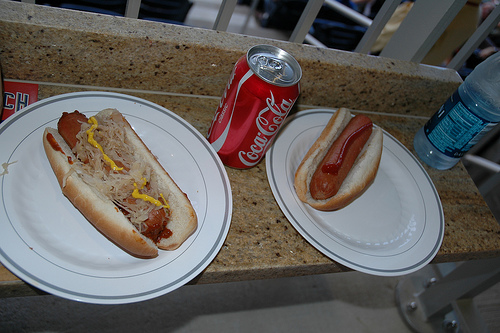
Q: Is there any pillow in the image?
A: No, there are no pillows.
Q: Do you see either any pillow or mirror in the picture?
A: No, there are no pillows or mirrors.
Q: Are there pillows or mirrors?
A: No, there are no pillows or mirrors.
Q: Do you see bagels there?
A: No, there are no bagels.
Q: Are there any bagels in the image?
A: No, there are no bagels.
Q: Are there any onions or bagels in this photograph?
A: No, there are no bagels or onions.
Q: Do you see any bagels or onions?
A: No, there are no bagels or onions.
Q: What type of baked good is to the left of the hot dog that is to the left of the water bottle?
A: The food is a bun.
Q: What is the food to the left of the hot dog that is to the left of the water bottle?
A: The food is a bun.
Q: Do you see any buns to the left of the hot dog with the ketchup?
A: Yes, there is a bun to the left of the hot dog.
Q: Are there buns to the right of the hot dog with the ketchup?
A: No, the bun is to the left of the hot dog.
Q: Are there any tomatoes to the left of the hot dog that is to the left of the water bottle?
A: No, there is a bun to the left of the hot dog.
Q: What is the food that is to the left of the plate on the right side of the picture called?
A: The food is a bun.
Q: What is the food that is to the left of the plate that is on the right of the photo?
A: The food is a bun.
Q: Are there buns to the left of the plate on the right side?
A: Yes, there is a bun to the left of the plate.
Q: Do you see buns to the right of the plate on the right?
A: No, the bun is to the left of the plate.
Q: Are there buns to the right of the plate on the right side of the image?
A: No, the bun is to the left of the plate.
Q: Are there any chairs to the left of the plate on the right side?
A: No, there is a bun to the left of the plate.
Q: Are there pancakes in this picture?
A: No, there are no pancakes.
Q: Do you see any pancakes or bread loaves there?
A: No, there are no pancakes or bread loaves.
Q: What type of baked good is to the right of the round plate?
A: The food is a bun.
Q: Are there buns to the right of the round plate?
A: Yes, there is a bun to the right of the plate.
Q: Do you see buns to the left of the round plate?
A: No, the bun is to the right of the plate.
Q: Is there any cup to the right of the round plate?
A: No, there is a bun to the right of the plate.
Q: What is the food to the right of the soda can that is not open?
A: The food is a bun.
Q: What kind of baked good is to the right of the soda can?
A: The food is a bun.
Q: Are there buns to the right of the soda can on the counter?
A: Yes, there is a bun to the right of the soda can.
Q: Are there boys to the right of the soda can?
A: No, there is a bun to the right of the soda can.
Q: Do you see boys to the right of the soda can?
A: No, there is a bun to the right of the soda can.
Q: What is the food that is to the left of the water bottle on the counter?
A: The food is a bun.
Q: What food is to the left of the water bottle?
A: The food is a bun.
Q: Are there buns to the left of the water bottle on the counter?
A: Yes, there is a bun to the left of the water bottle.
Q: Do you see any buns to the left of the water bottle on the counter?
A: Yes, there is a bun to the left of the water bottle.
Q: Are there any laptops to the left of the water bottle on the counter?
A: No, there is a bun to the left of the water bottle.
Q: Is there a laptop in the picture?
A: No, there are no laptops.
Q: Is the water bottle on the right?
A: Yes, the water bottle is on the right of the image.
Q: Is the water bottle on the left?
A: No, the water bottle is on the right of the image.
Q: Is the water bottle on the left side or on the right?
A: The water bottle is on the right of the image.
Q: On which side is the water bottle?
A: The water bottle is on the right of the image.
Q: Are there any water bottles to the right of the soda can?
A: Yes, there is a water bottle to the right of the soda can.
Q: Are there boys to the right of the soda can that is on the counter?
A: No, there is a water bottle to the right of the soda can.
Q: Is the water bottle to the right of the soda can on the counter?
A: Yes, the water bottle is to the right of the soda can.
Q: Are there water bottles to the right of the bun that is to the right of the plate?
A: Yes, there is a water bottle to the right of the bun.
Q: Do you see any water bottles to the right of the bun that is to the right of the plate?
A: Yes, there is a water bottle to the right of the bun.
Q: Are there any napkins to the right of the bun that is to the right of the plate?
A: No, there is a water bottle to the right of the bun.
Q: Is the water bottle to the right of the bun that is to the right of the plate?
A: Yes, the water bottle is to the right of the bun.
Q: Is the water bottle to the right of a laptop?
A: No, the water bottle is to the right of the bun.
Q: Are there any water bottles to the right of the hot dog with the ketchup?
A: Yes, there is a water bottle to the right of the hot dog.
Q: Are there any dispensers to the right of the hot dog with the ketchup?
A: No, there is a water bottle to the right of the hot dog.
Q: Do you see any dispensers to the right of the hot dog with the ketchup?
A: No, there is a water bottle to the right of the hot dog.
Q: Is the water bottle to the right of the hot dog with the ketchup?
A: Yes, the water bottle is to the right of the hot dog.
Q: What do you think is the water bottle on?
A: The water bottle is on the counter.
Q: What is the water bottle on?
A: The water bottle is on the counter.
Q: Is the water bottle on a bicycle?
A: No, the water bottle is on the counter.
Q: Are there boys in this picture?
A: No, there are no boys.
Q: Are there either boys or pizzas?
A: No, there are no boys or pizzas.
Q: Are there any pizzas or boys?
A: No, there are no boys or pizzas.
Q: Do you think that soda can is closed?
A: Yes, the soda can is closed.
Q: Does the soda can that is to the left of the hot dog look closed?
A: Yes, the soda can is closed.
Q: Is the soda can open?
A: No, the soda can is closed.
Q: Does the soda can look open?
A: No, the soda can is closed.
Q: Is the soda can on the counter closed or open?
A: The soda can is closed.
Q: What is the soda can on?
A: The soda can is on the counter.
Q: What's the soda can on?
A: The soda can is on the counter.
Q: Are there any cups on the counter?
A: No, there is a soda can on the counter.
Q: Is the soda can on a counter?
A: Yes, the soda can is on a counter.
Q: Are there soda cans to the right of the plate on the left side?
A: Yes, there is a soda can to the right of the plate.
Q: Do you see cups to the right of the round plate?
A: No, there is a soda can to the right of the plate.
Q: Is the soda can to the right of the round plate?
A: Yes, the soda can is to the right of the plate.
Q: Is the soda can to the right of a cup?
A: No, the soda can is to the right of the plate.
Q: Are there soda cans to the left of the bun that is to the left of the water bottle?
A: Yes, there is a soda can to the left of the bun.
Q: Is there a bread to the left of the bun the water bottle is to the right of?
A: No, there is a soda can to the left of the bun.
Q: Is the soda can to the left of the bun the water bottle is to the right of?
A: Yes, the soda can is to the left of the bun.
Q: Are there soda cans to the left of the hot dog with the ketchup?
A: Yes, there is a soda can to the left of the hot dog.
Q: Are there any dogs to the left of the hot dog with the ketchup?
A: No, there is a soda can to the left of the hot dog.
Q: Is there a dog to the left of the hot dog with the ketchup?
A: No, there is a soda can to the left of the hot dog.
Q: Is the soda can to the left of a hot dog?
A: Yes, the soda can is to the left of a hot dog.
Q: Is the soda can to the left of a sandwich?
A: No, the soda can is to the left of a hot dog.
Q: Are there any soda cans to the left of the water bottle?
A: Yes, there is a soda can to the left of the water bottle.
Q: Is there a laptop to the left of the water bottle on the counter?
A: No, there is a soda can to the left of the water bottle.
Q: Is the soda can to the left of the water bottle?
A: Yes, the soda can is to the left of the water bottle.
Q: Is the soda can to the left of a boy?
A: No, the soda can is to the left of the water bottle.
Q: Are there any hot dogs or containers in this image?
A: Yes, there is a hot dog.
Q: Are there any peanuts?
A: No, there are no peanuts.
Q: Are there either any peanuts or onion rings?
A: No, there are no peanuts or onion rings.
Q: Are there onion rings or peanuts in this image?
A: No, there are no peanuts or onion rings.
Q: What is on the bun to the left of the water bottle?
A: The hot dog is on the bun.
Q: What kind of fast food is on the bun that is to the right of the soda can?
A: The food is a hot dog.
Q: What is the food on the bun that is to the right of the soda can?
A: The food is a hot dog.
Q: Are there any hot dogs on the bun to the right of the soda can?
A: Yes, there is a hot dog on the bun.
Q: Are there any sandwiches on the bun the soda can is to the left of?
A: No, there is a hot dog on the bun.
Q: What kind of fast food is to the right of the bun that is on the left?
A: The food is a hot dog.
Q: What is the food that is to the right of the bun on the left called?
A: The food is a hot dog.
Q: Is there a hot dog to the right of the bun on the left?
A: Yes, there is a hot dog to the right of the bun.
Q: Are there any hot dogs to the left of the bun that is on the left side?
A: No, the hot dog is to the right of the bun.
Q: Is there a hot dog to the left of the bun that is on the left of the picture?
A: No, the hot dog is to the right of the bun.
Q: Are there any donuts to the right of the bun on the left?
A: No, there is a hot dog to the right of the bun.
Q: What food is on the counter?
A: The food is a hot dog.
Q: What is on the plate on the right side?
A: The hot dog is on the plate.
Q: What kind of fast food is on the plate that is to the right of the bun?
A: The food is a hot dog.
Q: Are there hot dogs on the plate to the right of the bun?
A: Yes, there is a hot dog on the plate.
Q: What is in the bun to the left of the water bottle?
A: The hot dog is in the bun.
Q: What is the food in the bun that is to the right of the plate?
A: The food is a hot dog.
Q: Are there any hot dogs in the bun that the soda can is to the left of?
A: Yes, there is a hot dog in the bun.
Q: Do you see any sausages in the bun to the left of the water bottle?
A: No, there is a hot dog in the bun.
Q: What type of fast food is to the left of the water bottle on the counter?
A: The food is a hot dog.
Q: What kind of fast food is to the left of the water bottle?
A: The food is a hot dog.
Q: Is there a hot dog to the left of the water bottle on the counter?
A: Yes, there is a hot dog to the left of the water bottle.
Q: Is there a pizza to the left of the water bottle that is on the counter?
A: No, there is a hot dog to the left of the water bottle.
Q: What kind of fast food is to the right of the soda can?
A: The food is a hot dog.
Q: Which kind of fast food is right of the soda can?
A: The food is a hot dog.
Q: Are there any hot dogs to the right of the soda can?
A: Yes, there is a hot dog to the right of the soda can.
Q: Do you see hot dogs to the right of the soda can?
A: Yes, there is a hot dog to the right of the soda can.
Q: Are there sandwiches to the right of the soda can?
A: No, there is a hot dog to the right of the soda can.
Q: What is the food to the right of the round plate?
A: The food is a hot dog.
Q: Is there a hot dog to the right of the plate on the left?
A: Yes, there is a hot dog to the right of the plate.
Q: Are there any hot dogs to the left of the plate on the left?
A: No, the hot dog is to the right of the plate.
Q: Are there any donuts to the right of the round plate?
A: No, there is a hot dog to the right of the plate.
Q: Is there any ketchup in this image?
A: Yes, there is ketchup.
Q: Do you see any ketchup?
A: Yes, there is ketchup.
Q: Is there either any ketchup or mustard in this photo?
A: Yes, there is ketchup.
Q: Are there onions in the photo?
A: No, there are no onions.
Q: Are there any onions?
A: No, there are no onions.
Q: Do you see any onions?
A: No, there are no onions.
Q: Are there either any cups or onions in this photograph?
A: No, there are no onions or cups.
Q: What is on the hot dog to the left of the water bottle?
A: The ketchup is on the hot dog.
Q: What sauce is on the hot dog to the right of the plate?
A: The sauce is ketchup.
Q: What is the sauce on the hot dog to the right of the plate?
A: The sauce is ketchup.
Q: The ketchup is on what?
A: The ketchup is on the hot dog.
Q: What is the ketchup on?
A: The ketchup is on the hot dog.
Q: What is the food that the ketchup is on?
A: The food is a hot dog.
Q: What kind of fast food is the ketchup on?
A: The ketchup is on the hot dog.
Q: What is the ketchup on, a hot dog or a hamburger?
A: The ketchup is on a hot dog.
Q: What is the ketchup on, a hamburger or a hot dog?
A: The ketchup is on a hot dog.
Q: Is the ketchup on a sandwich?
A: No, the ketchup is on the hot dog.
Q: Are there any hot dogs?
A: Yes, there is a hot dog.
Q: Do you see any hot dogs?
A: Yes, there is a hot dog.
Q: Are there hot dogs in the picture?
A: Yes, there is a hot dog.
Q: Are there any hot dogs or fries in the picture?
A: Yes, there is a hot dog.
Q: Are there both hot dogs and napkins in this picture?
A: No, there is a hot dog but no napkins.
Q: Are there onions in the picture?
A: No, there are no onions.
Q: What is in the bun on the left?
A: The hot dog is in the bun.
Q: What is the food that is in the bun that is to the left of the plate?
A: The food is a hot dog.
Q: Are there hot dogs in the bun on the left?
A: Yes, there is a hot dog in the bun.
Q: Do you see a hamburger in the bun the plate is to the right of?
A: No, there is a hot dog in the bun.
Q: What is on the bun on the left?
A: The hot dog is on the bun.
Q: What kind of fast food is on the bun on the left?
A: The food is a hot dog.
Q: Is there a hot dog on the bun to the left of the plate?
A: Yes, there is a hot dog on the bun.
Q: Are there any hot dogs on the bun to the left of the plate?
A: Yes, there is a hot dog on the bun.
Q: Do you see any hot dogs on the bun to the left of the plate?
A: Yes, there is a hot dog on the bun.